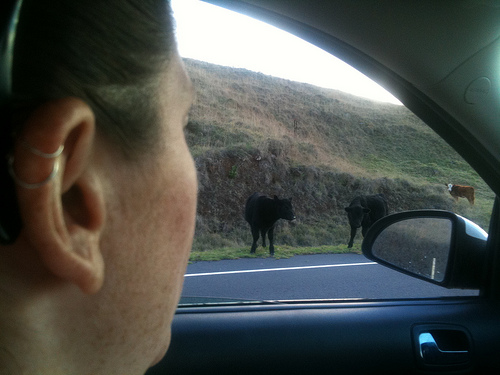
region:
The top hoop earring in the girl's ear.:
[25, 132, 67, 164]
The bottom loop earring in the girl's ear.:
[16, 163, 66, 192]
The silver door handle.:
[411, 328, 477, 360]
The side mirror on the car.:
[362, 203, 484, 292]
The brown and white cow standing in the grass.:
[443, 178, 486, 209]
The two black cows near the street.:
[233, 187, 393, 263]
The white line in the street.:
[184, 256, 387, 274]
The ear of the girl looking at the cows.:
[24, 101, 123, 308]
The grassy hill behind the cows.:
[211, 93, 471, 245]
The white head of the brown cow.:
[441, 182, 454, 191]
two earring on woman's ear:
[17, 115, 86, 227]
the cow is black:
[227, 172, 307, 257]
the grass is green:
[366, 140, 415, 167]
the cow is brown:
[434, 172, 489, 205]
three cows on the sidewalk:
[215, 161, 493, 255]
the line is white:
[247, 259, 339, 289]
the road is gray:
[288, 276, 394, 308]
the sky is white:
[216, 42, 296, 69]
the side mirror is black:
[333, 201, 498, 305]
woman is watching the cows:
[123, 77, 483, 297]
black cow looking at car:
[343, 191, 389, 248]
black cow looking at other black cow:
[243, 192, 297, 254]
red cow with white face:
[444, 180, 476, 205]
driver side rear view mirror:
[359, 208, 485, 289]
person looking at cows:
[5, 3, 197, 373]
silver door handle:
[411, 323, 471, 361]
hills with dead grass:
[178, 55, 492, 255]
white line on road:
[181, 262, 379, 277]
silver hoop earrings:
[6, 131, 63, 189]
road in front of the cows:
[180, 252, 477, 303]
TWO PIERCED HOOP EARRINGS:
[12, 137, 65, 194]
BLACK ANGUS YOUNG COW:
[237, 192, 297, 257]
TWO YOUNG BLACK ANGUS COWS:
[239, 192, 393, 252]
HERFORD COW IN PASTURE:
[444, 177, 476, 205]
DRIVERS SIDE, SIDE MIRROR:
[356, 208, 493, 285]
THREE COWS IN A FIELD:
[227, 179, 492, 248]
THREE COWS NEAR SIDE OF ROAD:
[235, 175, 477, 294]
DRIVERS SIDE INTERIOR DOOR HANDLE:
[410, 325, 480, 364]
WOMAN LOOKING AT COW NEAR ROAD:
[0, 0, 297, 369]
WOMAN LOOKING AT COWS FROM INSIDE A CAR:
[2, 4, 498, 305]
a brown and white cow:
[442, 180, 477, 210]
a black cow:
[240, 189, 297, 262]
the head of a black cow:
[272, 190, 297, 225]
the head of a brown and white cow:
[443, 181, 457, 193]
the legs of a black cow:
[246, 225, 278, 257]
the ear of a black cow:
[271, 192, 282, 203]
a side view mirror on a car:
[359, 204, 488, 294]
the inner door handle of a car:
[412, 322, 472, 363]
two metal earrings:
[6, 132, 64, 193]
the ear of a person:
[13, 92, 109, 297]